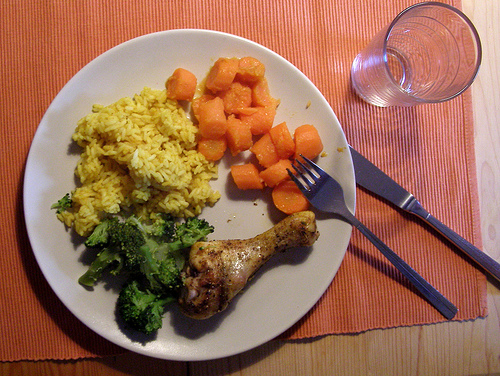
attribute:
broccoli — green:
[83, 218, 211, 335]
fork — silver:
[289, 161, 462, 320]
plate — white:
[23, 31, 355, 364]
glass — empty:
[353, 0, 480, 110]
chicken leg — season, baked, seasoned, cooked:
[180, 213, 318, 320]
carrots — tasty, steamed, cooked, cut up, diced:
[167, 57, 322, 211]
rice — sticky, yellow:
[61, 88, 218, 233]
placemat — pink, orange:
[1, 2, 488, 359]